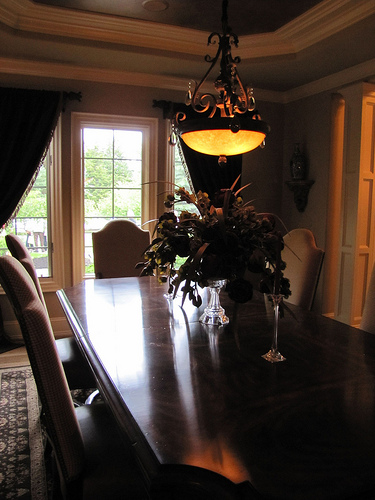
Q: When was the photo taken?
A: Daytime.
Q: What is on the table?
A: Flowers.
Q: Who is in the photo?
A: Nobody.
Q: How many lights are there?
A: One.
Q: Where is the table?
A: In the dining room.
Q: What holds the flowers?
A: A vase.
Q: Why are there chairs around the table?
A: So people can sit.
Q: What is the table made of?
A: Wood.